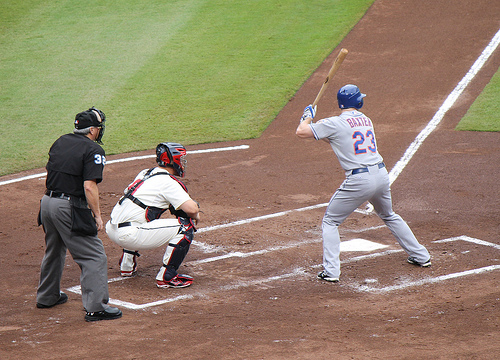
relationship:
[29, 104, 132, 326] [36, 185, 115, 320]
man wearing gray pants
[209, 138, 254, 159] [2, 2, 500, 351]
white line on field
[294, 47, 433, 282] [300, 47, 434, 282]
man has number 23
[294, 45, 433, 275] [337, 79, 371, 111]
man wearing a blue helmet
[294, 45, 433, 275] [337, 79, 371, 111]
person wearing a helmet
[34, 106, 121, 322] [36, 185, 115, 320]
man wearing gray pants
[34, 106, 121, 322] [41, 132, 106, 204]
man wearing black shirt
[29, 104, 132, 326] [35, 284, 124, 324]
man wearing black shoes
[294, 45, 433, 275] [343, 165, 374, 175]
man wearing a blue belt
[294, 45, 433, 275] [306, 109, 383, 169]
man wearing a gray jersey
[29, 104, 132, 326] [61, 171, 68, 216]
man wearing gray and black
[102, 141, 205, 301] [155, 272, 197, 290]
man wearing red black sneakers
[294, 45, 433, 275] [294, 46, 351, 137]
man holding bat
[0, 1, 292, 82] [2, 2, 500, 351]
grass on field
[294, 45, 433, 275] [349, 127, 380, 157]
man with number 23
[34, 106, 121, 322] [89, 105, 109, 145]
man wearing a face mask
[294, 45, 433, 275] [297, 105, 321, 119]
man wearing blue white gloves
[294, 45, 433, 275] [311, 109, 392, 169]
man wearing gray jersey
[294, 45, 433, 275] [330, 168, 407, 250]
man wearing gray pants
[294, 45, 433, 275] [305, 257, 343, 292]
man wearing tennis shoes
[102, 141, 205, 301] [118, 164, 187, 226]
man wearing a white shirt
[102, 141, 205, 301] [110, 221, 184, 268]
man wearing white pants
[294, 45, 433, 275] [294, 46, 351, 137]
baseball player at bat